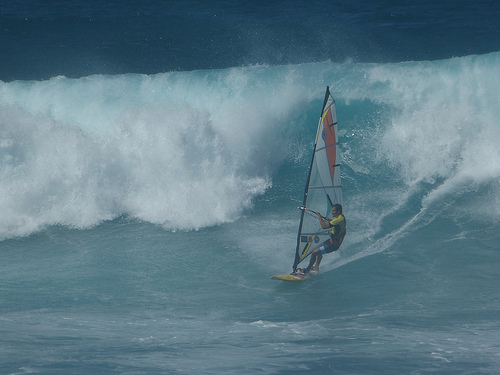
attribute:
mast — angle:
[301, 101, 343, 262]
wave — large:
[2, 60, 499, 238]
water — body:
[2, 51, 497, 371]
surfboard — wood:
[269, 263, 349, 284]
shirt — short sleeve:
[328, 218, 349, 241]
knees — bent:
[295, 238, 327, 261]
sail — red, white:
[285, 89, 339, 264]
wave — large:
[108, 89, 472, 336]